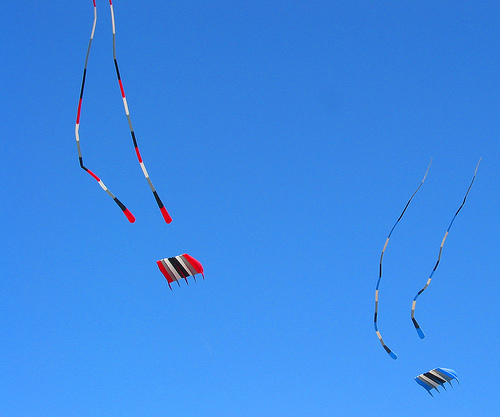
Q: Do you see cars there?
A: No, there are no cars.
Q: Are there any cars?
A: No, there are no cars.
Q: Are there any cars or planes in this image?
A: No, there are no cars or planes.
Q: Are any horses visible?
A: No, there are no horses.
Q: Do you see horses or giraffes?
A: No, there are no horses or giraffes.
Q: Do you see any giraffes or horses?
A: No, there are no horses or giraffes.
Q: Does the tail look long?
A: Yes, the tail is long.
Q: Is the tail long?
A: Yes, the tail is long.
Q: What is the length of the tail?
A: The tail is long.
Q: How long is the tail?
A: The tail is long.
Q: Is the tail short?
A: No, the tail is long.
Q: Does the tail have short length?
A: No, the tail is long.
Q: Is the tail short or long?
A: The tail is long.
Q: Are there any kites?
A: Yes, there is a kite.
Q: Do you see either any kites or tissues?
A: Yes, there is a kite.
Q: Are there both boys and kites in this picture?
A: No, there is a kite but no boys.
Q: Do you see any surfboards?
A: No, there are no surfboards.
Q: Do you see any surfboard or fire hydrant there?
A: No, there are no surfboards or fire hydrants.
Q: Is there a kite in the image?
A: Yes, there is a kite.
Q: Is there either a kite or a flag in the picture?
A: Yes, there is a kite.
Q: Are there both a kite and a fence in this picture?
A: No, there is a kite but no fences.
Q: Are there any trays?
A: No, there are no trays.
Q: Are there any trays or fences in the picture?
A: No, there are no trays or fences.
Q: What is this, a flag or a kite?
A: This is a kite.